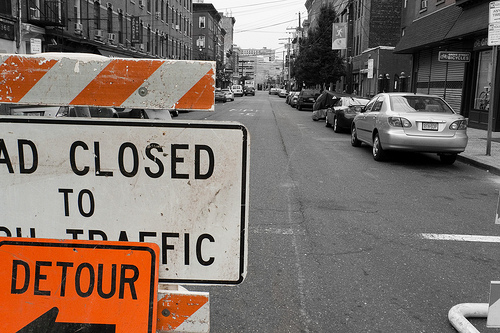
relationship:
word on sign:
[66, 140, 217, 181] [0, 115, 251, 287]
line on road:
[419, 233, 499, 243] [301, 176, 481, 322]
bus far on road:
[240, 72, 263, 98] [252, 80, 329, 223]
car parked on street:
[350, 92, 469, 164] [173, 92, 499, 332]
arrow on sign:
[11, 306, 116, 332] [0, 238, 158, 330]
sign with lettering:
[0, 115, 251, 287] [0, 136, 213, 261]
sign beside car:
[485, 0, 499, 154] [348, 91, 470, 166]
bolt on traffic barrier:
[138, 86, 148, 96] [0, 48, 249, 328]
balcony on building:
[0, 1, 70, 25] [0, 1, 196, 100]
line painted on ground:
[422, 227, 496, 245] [313, 172, 483, 276]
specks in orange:
[3, 56, 135, 111] [113, 57, 133, 95]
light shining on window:
[387, 91, 407, 111] [385, 95, 452, 114]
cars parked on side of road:
[265, 76, 493, 177] [228, 113, 460, 323]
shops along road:
[302, 44, 498, 141] [228, 99, 433, 331]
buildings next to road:
[0, 0, 235, 85] [170, 90, 499, 332]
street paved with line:
[253, 100, 498, 310] [419, 233, 499, 243]